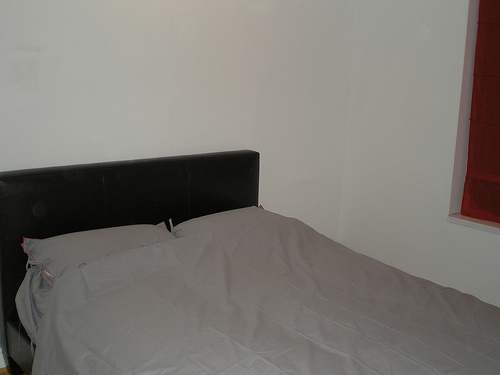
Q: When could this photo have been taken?
A: Bedtime.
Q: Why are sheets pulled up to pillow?
A: Noone in bed yet.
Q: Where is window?
A: To right of bed.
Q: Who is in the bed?
A: Noone.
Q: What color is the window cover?
A: Dark orange.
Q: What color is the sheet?
A: White.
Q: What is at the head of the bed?
A: Headboard.